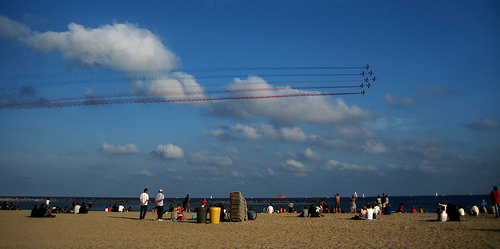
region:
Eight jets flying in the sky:
[354, 61, 379, 98]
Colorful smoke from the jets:
[0, 58, 365, 125]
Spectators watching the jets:
[3, 182, 498, 232]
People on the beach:
[3, 184, 498, 226]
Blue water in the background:
[5, 193, 499, 218]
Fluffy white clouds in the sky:
[4, 13, 489, 194]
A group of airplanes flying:
[355, 56, 382, 104]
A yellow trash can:
[207, 204, 223, 226]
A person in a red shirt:
[400, 201, 405, 212]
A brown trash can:
[195, 207, 210, 222]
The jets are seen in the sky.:
[353, 50, 400, 115]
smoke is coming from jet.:
[308, 48, 383, 128]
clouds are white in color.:
[51, 22, 193, 139]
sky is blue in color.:
[381, 17, 453, 87]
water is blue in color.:
[400, 194, 452, 209]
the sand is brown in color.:
[260, 224, 329, 244]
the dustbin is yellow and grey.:
[194, 202, 238, 239]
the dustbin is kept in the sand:
[186, 202, 230, 236]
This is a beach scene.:
[13, 184, 479, 225]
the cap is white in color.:
[153, 186, 164, 200]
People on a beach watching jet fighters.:
[15, 27, 490, 233]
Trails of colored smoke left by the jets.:
[15, 55, 356, 105]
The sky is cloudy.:
[70, 35, 355, 185]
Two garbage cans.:
[195, 205, 220, 227]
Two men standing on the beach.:
[130, 175, 165, 221]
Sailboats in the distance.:
[265, 147, 465, 202]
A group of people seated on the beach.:
[20, 185, 96, 230]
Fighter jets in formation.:
[350, 60, 390, 110]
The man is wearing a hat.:
[150, 185, 165, 220]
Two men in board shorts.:
[330, 190, 356, 215]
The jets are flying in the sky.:
[356, 58, 403, 108]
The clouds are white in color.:
[74, 25, 203, 100]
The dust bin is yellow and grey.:
[195, 201, 221, 229]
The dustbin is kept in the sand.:
[191, 202, 229, 226]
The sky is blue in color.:
[397, 21, 487, 93]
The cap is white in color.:
[154, 183, 171, 198]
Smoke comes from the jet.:
[320, 56, 380, 113]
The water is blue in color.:
[407, 193, 452, 204]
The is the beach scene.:
[11, 185, 468, 245]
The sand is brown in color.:
[252, 222, 354, 247]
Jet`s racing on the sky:
[348, 47, 387, 97]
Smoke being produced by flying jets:
[8, 52, 367, 112]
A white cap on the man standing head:
[158, 186, 166, 195]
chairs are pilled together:
[220, 190, 275, 222]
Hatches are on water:
[345, 180, 371, 195]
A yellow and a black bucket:
[190, 192, 225, 227]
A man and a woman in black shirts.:
[21, 190, 62, 220]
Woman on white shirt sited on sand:
[435, 201, 445, 221]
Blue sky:
[335, 17, 405, 52]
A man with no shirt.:
[327, 190, 343, 215]